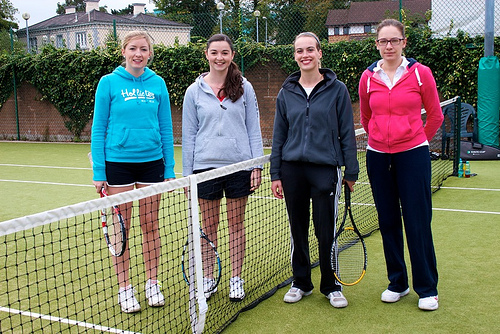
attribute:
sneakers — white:
[383, 284, 442, 309]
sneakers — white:
[277, 277, 352, 309]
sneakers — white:
[187, 267, 244, 302]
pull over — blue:
[90, 62, 177, 183]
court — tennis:
[0, 127, 500, 328]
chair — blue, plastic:
[441, 102, 478, 154]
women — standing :
[70, 15, 457, 313]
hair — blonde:
[114, 20, 156, 45]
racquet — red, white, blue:
[84, 149, 129, 257]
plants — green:
[11, 34, 478, 79]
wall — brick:
[4, 88, 468, 143]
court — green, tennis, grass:
[4, 140, 484, 331]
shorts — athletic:
[104, 158, 167, 187]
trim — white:
[106, 180, 165, 182]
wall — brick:
[7, 84, 93, 144]